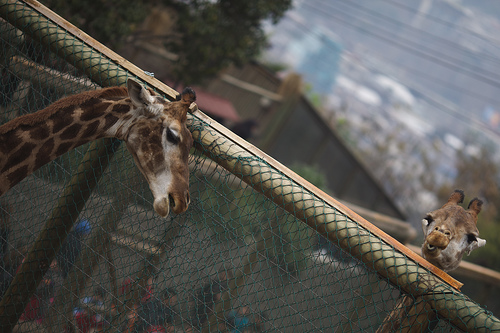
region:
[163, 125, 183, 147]
the black eye of a giraffee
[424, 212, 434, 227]
the black eye of a giraffee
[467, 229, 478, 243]
the black eye of a giraffee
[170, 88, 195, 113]
the horn of the giraffe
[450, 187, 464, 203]
the horn of the giraffe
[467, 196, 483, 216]
the horn of the giraffe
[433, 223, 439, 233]
the nostril of the giraffe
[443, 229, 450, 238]
the nostril of the giraffe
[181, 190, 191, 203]
the nostril of the giraffe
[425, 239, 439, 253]
the mouth of the giraffe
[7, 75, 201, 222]
giraffee scratching his head on the top of a fence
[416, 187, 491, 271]
giraffee looking over a fence and making a "sour-puss" puckered face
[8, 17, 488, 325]
partial wire fencing with green wire and wood poles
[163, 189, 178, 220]
slightly open giraffee mouth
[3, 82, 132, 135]
upper portion of giraffee mane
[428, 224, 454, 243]
giraffee nose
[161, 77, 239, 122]
red awning on brown building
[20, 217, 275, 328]
many indistinguishable people watching through the fence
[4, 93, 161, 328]
wooden fence pole with a giraffee standing in front of it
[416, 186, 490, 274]
brown and white giraffee with twisted mouth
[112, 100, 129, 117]
brown spot on giraffe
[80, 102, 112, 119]
brown spot on giraffe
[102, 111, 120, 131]
brown spot on giraffe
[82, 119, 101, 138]
brown spot on giraffe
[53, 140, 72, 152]
brown spot on giraffe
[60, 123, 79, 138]
brown spot on giraffe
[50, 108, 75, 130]
brown spot on giraffe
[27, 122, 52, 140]
brown spot on giraffe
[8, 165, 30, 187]
brown spot on giraffe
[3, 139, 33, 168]
brown spot on giraffe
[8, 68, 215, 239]
brown giraffe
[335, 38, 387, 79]
white clouds in blue sky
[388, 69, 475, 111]
white clouds in blue sky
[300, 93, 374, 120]
white clouds in blue sky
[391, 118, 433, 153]
white clouds in blue sky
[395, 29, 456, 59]
white clouds in blue sky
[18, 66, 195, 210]
giraffe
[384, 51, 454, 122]
white clouds in blue sky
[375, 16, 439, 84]
white clouds in blue sky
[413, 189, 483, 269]
Face on a giraffe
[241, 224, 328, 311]
Fence made of metal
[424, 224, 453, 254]
Nose on a giraffe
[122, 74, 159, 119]
Ear on a giraffe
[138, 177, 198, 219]
Mouth on a giraffe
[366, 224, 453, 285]
Wood on top of a fence